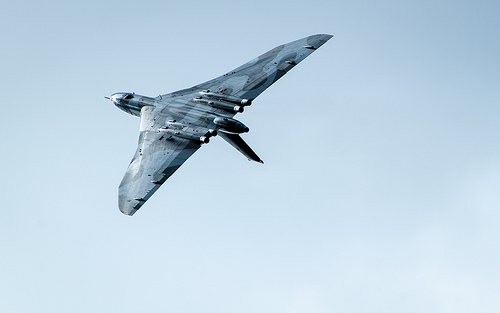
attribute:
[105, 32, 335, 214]
jet — flying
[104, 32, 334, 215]
airplane — flying , upside down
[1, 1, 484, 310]
sky — clear, blue